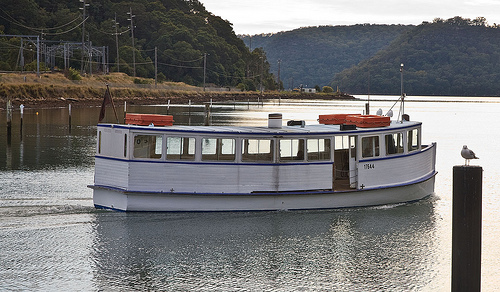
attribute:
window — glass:
[179, 132, 269, 170]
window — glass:
[279, 135, 306, 164]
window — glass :
[253, 134, 280, 161]